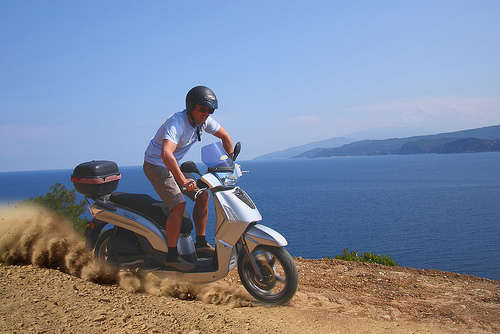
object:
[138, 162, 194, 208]
shorts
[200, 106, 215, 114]
sunglasses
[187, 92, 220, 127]
face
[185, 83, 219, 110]
helmet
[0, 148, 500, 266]
ocean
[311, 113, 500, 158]
mountains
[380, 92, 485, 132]
white clouds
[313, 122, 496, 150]
mountain range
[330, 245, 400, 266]
patch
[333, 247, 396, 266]
grass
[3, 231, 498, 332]
dirt road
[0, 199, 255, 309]
dirt plume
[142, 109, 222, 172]
shirt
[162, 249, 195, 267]
shoes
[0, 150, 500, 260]
water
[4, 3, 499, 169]
sky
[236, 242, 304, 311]
tire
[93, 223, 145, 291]
tire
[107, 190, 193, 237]
black seat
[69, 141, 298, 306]
moped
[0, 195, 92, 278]
dirt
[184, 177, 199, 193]
hand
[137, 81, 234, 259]
man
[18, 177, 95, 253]
tree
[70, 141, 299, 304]
scooter